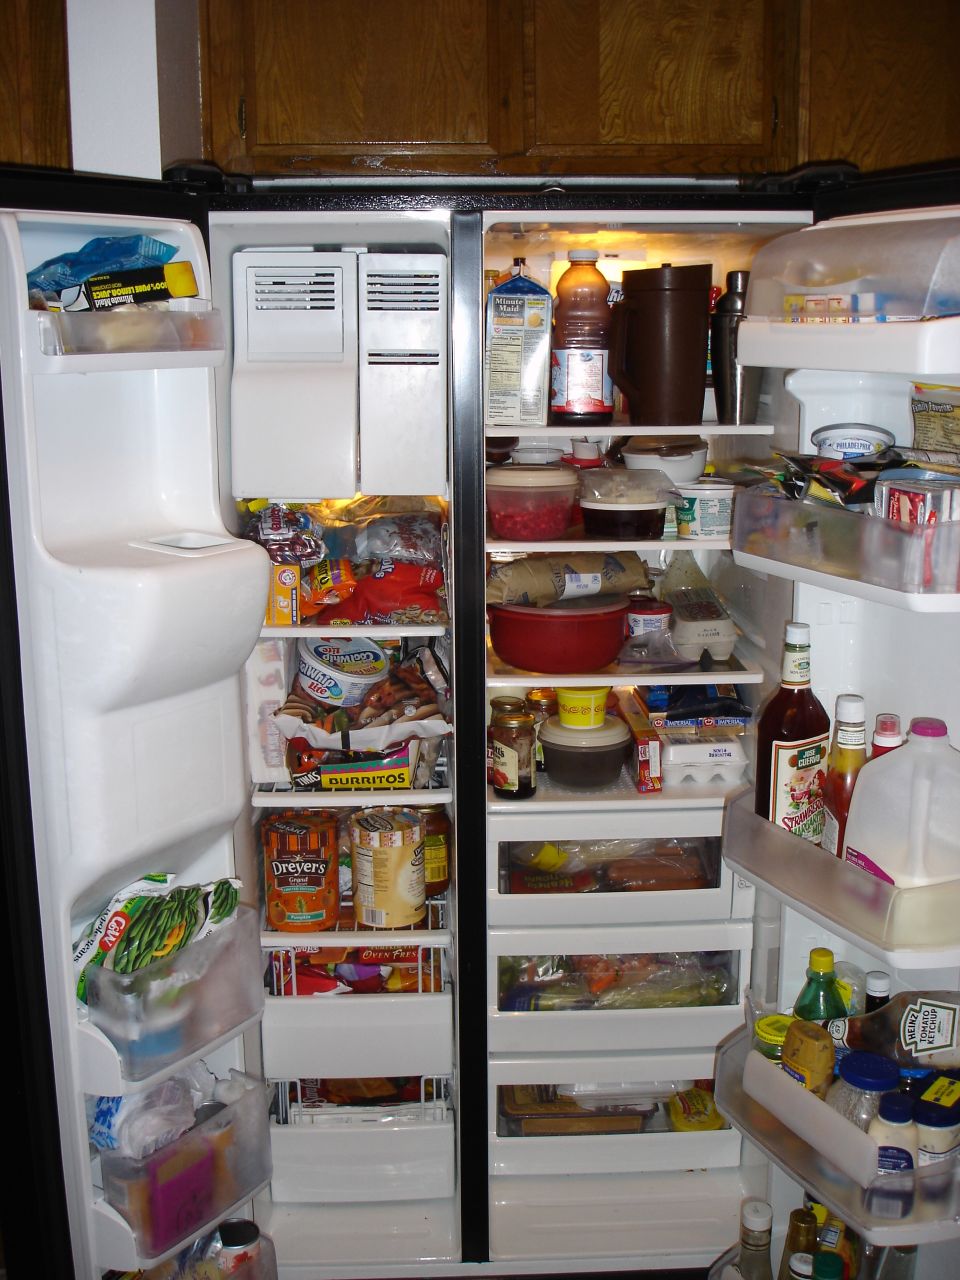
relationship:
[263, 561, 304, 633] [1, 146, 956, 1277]
baking soda in fridge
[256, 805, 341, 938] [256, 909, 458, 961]
ice cream on shelf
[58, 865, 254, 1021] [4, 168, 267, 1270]
green beans on door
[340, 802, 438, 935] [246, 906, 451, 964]
ice cream sits on shelf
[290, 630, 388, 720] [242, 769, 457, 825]
whip cream on shelf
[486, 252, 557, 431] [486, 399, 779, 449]
orange juice sits on shelf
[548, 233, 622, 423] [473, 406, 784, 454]
juice sits on shelf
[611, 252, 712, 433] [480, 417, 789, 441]
juice sits on shelf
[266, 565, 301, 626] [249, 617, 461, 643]
baking soda sits on shelf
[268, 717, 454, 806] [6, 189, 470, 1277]
burritos in freezer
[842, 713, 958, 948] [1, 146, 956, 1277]
milk in fridge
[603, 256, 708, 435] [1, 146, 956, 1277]
brown pitcher in fridge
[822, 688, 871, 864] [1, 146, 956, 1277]
ketchup bottle in fridge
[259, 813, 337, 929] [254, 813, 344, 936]
container of dreyer's ice-cream